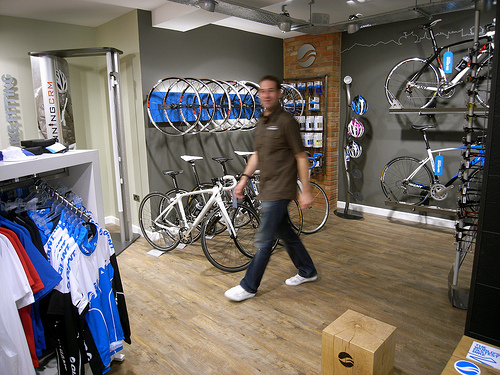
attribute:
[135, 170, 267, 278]
bicycle — white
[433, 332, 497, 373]
box — small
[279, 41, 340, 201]
metal logo — metallic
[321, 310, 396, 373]
box — small, cardboard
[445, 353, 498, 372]
sticker — blue, white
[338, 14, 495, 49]
design — white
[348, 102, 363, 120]
helmet — bike, blue, white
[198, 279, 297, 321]
shoe — white, athletic shoe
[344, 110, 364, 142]
helmet — pink, white, bike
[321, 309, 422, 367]
block — wooden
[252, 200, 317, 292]
jeans — blue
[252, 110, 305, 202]
shirt — brown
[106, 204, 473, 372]
floor — wooden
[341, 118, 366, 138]
helmet — blue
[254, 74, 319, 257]
man — walking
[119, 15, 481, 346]
store — bike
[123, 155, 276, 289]
speed bike — white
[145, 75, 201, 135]
tire — hanging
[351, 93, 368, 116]
helmet — hanging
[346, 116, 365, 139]
helmet — hanging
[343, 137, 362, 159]
helmet — hanging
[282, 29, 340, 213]
wall — brick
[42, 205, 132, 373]
suits — bike, blue, white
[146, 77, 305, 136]
tires — bicycle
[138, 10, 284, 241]
wall — grey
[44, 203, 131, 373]
shirts — hanging